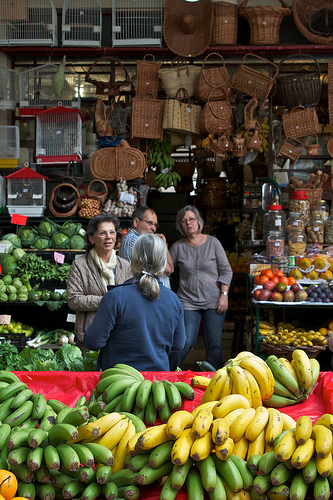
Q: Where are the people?
A: A market.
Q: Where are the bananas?
A: On table.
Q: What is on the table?
A: Red tablecloth.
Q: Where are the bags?
A: Over the man and woman.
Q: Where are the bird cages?
A: Over vegetables.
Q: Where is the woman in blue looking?
A: Away.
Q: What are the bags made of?
A: Wicker.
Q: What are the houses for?
A: Birds.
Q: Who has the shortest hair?
A: The man with glasses.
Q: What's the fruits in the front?
A: Bananas.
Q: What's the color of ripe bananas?
A: Yellow.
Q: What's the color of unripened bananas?
A: Green.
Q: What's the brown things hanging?
A: Baskets.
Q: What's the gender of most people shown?
A: Female.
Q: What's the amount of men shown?
A: One.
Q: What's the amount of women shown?
A: Three.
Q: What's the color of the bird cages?
A: White.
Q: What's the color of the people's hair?
A: Gray.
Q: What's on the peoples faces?
A: Glasses.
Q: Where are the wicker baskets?
A: Hanging above the store.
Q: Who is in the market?
A: Four people.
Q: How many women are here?
A: Three.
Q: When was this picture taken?
A: Daytime.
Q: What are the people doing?
A: Shopping.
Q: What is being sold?
A: Fruit.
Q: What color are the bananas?
A: Yellow.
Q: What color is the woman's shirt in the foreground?
A: Blue.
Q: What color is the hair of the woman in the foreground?
A: Grey.